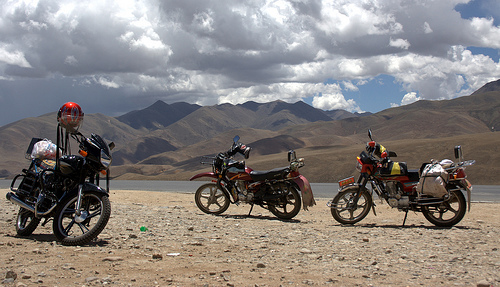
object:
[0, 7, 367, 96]
clouds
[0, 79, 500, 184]
mountain top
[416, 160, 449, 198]
bag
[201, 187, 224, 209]
spokes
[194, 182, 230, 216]
tire wheel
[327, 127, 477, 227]
bike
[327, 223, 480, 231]
shadow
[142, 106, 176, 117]
darkness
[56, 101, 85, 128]
helmet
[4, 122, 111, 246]
bike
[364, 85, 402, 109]
space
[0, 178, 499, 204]
river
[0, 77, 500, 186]
mountainous area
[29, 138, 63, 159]
bag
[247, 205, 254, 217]
shore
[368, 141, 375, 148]
accents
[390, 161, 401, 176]
paint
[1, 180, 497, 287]
ground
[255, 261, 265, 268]
rock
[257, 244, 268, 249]
rock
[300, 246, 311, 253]
rock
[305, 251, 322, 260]
rock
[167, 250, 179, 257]
rock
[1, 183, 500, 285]
road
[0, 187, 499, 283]
dirt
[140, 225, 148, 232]
bottle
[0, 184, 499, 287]
gravel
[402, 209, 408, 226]
kickstand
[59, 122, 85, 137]
handlebar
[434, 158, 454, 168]
storage pack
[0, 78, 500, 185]
mountain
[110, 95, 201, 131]
area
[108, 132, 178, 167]
area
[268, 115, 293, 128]
area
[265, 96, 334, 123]
area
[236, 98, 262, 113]
area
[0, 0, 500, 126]
sky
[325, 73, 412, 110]
patch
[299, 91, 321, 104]
patch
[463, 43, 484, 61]
patch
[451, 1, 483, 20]
patch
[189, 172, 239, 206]
front fender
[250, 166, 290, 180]
seat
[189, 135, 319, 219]
motorcycle